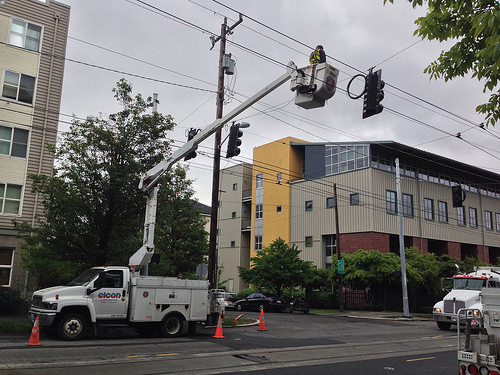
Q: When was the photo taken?
A: Daytime.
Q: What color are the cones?
A: Orange and white.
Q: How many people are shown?
A: One.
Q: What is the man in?
A: Bucket truck.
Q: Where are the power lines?
A: Overhead.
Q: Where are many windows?
A: Buildings.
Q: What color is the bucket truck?
A: White.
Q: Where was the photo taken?
A: At a stoplight.